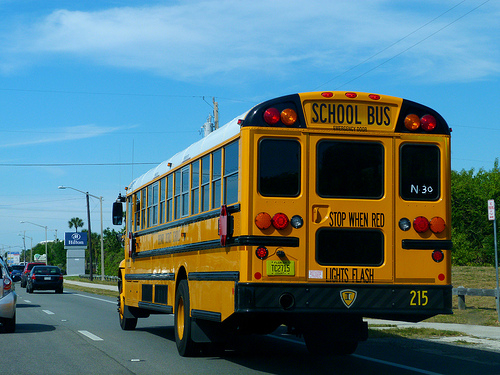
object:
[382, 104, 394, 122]
words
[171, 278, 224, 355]
tire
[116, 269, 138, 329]
tire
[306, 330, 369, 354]
tire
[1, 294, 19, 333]
tire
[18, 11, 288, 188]
sky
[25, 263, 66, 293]
car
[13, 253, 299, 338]
traffic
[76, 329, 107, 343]
line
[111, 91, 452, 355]
automobile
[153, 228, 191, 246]
signs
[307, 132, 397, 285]
back door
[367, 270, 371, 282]
words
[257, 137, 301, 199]
window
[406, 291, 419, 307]
number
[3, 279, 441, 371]
road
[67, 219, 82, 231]
palm tree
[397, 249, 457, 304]
bus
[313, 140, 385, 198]
windows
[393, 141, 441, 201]
windows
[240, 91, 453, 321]
back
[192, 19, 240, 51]
clouds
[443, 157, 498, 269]
leaves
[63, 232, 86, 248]
sign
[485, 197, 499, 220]
sign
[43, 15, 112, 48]
cloud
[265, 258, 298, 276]
license plate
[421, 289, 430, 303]
number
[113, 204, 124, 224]
mirror